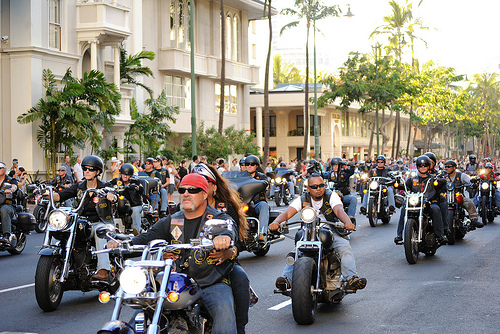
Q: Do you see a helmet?
A: Yes, there is a helmet.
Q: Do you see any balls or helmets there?
A: Yes, there is a helmet.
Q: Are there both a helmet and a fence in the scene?
A: No, there is a helmet but no fences.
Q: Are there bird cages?
A: No, there are no bird cages.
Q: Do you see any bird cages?
A: No, there are no bird cages.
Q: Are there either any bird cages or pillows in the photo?
A: No, there are no bird cages or pillows.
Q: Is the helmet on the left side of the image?
A: Yes, the helmet is on the left of the image.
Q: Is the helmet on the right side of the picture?
A: No, the helmet is on the left of the image.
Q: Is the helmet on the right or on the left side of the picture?
A: The helmet is on the left of the image.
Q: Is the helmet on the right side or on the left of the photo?
A: The helmet is on the left of the image.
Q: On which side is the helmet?
A: The helmet is on the left of the image.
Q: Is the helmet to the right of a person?
A: No, the helmet is to the left of a person.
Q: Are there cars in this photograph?
A: No, there are no cars.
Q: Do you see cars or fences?
A: No, there are no cars or fences.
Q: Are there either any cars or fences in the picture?
A: No, there are no cars or fences.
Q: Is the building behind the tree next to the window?
A: Yes, the building is behind the tree.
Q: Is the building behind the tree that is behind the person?
A: Yes, the building is behind the tree.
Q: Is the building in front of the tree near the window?
A: No, the building is behind the tree.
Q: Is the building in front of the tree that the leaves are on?
A: No, the building is behind the tree.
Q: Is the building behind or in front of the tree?
A: The building is behind the tree.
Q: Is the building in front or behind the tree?
A: The building is behind the tree.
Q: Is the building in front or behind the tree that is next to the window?
A: The building is behind the tree.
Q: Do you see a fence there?
A: No, there are no fences.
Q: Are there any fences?
A: No, there are no fences.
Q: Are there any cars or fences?
A: No, there are no fences or cars.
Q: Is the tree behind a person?
A: Yes, the tree is behind a person.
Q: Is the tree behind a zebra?
A: No, the tree is behind a person.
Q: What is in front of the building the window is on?
A: The tree is in front of the building.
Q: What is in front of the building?
A: The tree is in front of the building.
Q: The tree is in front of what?
A: The tree is in front of the building.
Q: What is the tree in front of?
A: The tree is in front of the building.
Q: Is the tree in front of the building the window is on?
A: Yes, the tree is in front of the building.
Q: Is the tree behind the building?
A: No, the tree is in front of the building.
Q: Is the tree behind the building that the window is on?
A: No, the tree is in front of the building.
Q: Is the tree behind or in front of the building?
A: The tree is in front of the building.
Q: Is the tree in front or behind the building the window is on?
A: The tree is in front of the building.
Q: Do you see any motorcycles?
A: Yes, there is a motorcycle.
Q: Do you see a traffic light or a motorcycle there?
A: Yes, there is a motorcycle.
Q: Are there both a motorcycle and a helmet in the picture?
A: Yes, there are both a motorcycle and a helmet.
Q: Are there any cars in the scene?
A: No, there are no cars.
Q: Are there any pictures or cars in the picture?
A: No, there are no cars or pictures.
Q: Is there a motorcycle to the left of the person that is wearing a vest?
A: Yes, there is a motorcycle to the left of the person.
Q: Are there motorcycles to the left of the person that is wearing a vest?
A: Yes, there is a motorcycle to the left of the person.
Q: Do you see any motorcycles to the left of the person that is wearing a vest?
A: Yes, there is a motorcycle to the left of the person.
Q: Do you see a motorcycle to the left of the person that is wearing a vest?
A: Yes, there is a motorcycle to the left of the person.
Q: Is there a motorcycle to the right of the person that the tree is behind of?
A: No, the motorcycle is to the left of the person.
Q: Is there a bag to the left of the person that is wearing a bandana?
A: No, there is a motorcycle to the left of the person.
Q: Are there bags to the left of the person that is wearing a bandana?
A: No, there is a motorcycle to the left of the person.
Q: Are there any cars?
A: No, there are no cars.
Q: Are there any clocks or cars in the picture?
A: No, there are no cars or clocks.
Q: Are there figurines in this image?
A: No, there are no figurines.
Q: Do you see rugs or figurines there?
A: No, there are no figurines or rugs.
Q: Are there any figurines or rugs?
A: No, there are no figurines or rugs.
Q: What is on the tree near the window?
A: The leaves are on the tree.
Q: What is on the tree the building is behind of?
A: The leaves are on the tree.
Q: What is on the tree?
A: The leaves are on the tree.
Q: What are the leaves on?
A: The leaves are on the tree.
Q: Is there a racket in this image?
A: No, there are no rackets.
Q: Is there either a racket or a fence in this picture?
A: No, there are no rackets or fences.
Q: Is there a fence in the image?
A: No, there are no fences.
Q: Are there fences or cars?
A: No, there are no fences or cars.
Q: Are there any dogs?
A: No, there are no dogs.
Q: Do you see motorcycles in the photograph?
A: Yes, there is a motorcycle.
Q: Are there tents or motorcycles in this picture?
A: Yes, there is a motorcycle.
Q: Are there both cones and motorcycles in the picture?
A: No, there is a motorcycle but no cones.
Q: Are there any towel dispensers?
A: No, there are no towel dispensers.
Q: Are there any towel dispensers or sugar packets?
A: No, there are no towel dispensers or sugar packets.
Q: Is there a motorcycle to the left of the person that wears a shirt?
A: Yes, there is a motorcycle to the left of the person.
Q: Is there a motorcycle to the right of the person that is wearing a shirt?
A: No, the motorcycle is to the left of the person.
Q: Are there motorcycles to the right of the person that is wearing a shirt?
A: No, the motorcycle is to the left of the person.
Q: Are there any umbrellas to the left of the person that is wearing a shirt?
A: No, there is a motorcycle to the left of the person.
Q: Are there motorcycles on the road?
A: Yes, there is a motorcycle on the road.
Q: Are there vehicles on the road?
A: No, there is a motorcycle on the road.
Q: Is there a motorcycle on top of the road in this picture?
A: Yes, there is a motorcycle on top of the road.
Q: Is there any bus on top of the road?
A: No, there is a motorcycle on top of the road.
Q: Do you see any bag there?
A: No, there are no bags.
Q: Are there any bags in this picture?
A: No, there are no bags.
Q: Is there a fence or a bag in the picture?
A: No, there are no bags or fences.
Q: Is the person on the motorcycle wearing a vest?
A: Yes, the person is wearing a vest.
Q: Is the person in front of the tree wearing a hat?
A: No, the person is wearing a vest.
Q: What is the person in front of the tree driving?
A: The person is driving a motorcycle.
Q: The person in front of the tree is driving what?
A: The person is driving a motorcycle.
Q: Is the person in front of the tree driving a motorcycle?
A: Yes, the person is driving a motorcycle.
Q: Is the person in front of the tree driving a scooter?
A: No, the person is driving a motorcycle.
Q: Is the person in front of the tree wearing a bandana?
A: Yes, the person is wearing a bandana.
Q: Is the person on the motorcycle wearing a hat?
A: No, the person is wearing a bandana.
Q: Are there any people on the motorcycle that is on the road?
A: Yes, there is a person on the motorbike.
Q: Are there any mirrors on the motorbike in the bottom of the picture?
A: No, there is a person on the motorbike.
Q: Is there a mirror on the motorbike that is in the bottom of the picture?
A: No, there is a person on the motorbike.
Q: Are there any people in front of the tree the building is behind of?
A: Yes, there is a person in front of the tree.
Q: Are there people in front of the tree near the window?
A: Yes, there is a person in front of the tree.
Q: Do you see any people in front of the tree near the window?
A: Yes, there is a person in front of the tree.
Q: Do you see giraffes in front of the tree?
A: No, there is a person in front of the tree.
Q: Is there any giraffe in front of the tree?
A: No, there is a person in front of the tree.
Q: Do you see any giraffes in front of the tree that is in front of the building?
A: No, there is a person in front of the tree.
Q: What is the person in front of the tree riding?
A: The person is riding a motorcycle.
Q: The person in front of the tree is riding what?
A: The person is riding a motorcycle.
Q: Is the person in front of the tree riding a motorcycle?
A: Yes, the person is riding a motorcycle.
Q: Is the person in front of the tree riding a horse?
A: No, the person is riding a motorcycle.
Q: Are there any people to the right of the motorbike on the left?
A: Yes, there is a person to the right of the motorcycle.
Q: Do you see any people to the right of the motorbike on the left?
A: Yes, there is a person to the right of the motorcycle.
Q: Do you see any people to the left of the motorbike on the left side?
A: No, the person is to the right of the motorcycle.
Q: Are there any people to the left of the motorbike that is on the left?
A: No, the person is to the right of the motorcycle.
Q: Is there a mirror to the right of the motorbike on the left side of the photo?
A: No, there is a person to the right of the motorbike.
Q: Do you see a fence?
A: No, there are no fences.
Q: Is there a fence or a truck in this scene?
A: No, there are no fences or trucks.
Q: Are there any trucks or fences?
A: No, there are no fences or trucks.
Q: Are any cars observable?
A: No, there are no cars.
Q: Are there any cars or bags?
A: No, there are no cars or bags.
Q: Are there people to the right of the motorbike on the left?
A: Yes, there is a person to the right of the motorbike.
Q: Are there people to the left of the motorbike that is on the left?
A: No, the person is to the right of the motorcycle.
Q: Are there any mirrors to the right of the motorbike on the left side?
A: No, there is a person to the right of the motorcycle.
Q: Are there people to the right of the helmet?
A: Yes, there is a person to the right of the helmet.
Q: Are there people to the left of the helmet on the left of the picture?
A: No, the person is to the right of the helmet.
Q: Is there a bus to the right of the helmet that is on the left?
A: No, there is a person to the right of the helmet.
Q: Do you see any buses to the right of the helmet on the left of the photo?
A: No, there is a person to the right of the helmet.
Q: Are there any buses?
A: No, there are no buses.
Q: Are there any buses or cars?
A: No, there are no buses or cars.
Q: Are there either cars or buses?
A: No, there are no buses or cars.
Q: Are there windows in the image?
A: Yes, there is a window.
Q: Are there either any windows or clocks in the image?
A: Yes, there is a window.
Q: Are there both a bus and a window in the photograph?
A: No, there is a window but no buses.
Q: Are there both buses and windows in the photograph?
A: No, there is a window but no buses.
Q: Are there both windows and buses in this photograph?
A: No, there is a window but no buses.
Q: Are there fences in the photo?
A: No, there are no fences.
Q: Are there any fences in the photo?
A: No, there are no fences.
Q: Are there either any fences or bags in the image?
A: No, there are no fences or bags.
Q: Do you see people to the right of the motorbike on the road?
A: Yes, there is a person to the right of the motorcycle.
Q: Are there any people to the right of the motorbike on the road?
A: Yes, there is a person to the right of the motorcycle.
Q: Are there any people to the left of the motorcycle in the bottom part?
A: No, the person is to the right of the motorcycle.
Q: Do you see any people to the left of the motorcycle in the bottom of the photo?
A: No, the person is to the right of the motorcycle.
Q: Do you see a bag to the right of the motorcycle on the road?
A: No, there is a person to the right of the motorbike.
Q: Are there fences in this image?
A: No, there are no fences.